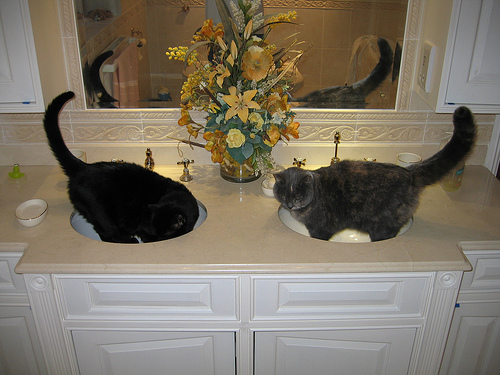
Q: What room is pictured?
A: It is a bathroom.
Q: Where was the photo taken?
A: It was taken at the bathroom.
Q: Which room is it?
A: It is a bathroom.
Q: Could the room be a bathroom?
A: Yes, it is a bathroom.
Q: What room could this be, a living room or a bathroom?
A: It is a bathroom.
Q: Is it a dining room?
A: No, it is a bathroom.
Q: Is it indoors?
A: Yes, it is indoors.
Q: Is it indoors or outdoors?
A: It is indoors.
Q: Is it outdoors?
A: No, it is indoors.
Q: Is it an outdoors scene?
A: No, it is indoors.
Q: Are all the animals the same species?
A: Yes, all the animals are cats.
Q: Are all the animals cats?
A: Yes, all the animals are cats.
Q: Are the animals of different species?
A: No, all the animals are cats.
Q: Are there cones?
A: No, there are no cones.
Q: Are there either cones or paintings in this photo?
A: No, there are no cones or paintings.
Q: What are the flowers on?
A: The flowers are on the counter.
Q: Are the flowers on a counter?
A: Yes, the flowers are on a counter.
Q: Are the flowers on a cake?
A: No, the flowers are on a counter.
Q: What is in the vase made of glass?
A: The flowers are in the vase.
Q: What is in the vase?
A: The flowers are in the vase.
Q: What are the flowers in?
A: The flowers are in the vase.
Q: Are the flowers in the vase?
A: Yes, the flowers are in the vase.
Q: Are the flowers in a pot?
A: No, the flowers are in the vase.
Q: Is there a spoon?
A: No, there are no spoons.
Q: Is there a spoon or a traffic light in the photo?
A: No, there are no spoons or traffic lights.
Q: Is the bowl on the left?
A: Yes, the bowl is on the left of the image.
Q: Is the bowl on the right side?
A: No, the bowl is on the left of the image.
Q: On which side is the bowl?
A: The bowl is on the left of the image.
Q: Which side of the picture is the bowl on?
A: The bowl is on the left of the image.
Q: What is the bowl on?
A: The bowl is on the counter.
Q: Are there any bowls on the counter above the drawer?
A: Yes, there is a bowl on the counter.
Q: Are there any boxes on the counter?
A: No, there is a bowl on the counter.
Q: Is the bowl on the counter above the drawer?
A: Yes, the bowl is on the counter.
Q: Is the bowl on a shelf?
A: No, the bowl is on the counter.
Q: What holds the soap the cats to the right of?
A: The bowl holds the soap.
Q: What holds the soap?
A: The bowl holds the soap.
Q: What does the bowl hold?
A: The bowl holds the soap.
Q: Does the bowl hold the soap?
A: Yes, the bowl holds the soap.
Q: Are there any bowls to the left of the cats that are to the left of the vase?
A: Yes, there is a bowl to the left of the cats.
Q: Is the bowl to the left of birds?
A: No, the bowl is to the left of the cats.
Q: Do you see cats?
A: Yes, there are cats.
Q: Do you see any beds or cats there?
A: Yes, there are cats.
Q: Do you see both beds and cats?
A: No, there are cats but no beds.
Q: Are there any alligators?
A: No, there are no alligators.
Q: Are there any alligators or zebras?
A: No, there are no alligators or zebras.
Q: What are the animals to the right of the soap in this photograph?
A: The animals are cats.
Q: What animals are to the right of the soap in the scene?
A: The animals are cats.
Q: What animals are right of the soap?
A: The animals are cats.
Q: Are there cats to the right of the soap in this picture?
A: Yes, there are cats to the right of the soap.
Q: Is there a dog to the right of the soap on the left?
A: No, there are cats to the right of the soap.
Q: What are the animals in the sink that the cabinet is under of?
A: The animals are cats.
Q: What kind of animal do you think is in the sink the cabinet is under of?
A: The animals are cats.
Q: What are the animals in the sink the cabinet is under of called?
A: The animals are cats.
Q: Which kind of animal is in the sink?
A: The animals are cats.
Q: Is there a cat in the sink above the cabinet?
A: Yes, there are cats in the sink.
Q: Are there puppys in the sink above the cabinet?
A: No, there are cats in the sink.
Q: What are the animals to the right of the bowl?
A: The animals are cats.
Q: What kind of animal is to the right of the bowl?
A: The animals are cats.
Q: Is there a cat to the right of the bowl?
A: Yes, there are cats to the right of the bowl.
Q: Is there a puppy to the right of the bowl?
A: No, there are cats to the right of the bowl.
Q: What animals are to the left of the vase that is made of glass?
A: The animals are cats.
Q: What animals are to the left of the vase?
A: The animals are cats.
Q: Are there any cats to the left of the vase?
A: Yes, there are cats to the left of the vase.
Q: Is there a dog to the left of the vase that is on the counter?
A: No, there are cats to the left of the vase.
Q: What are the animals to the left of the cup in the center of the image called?
A: The animals are cats.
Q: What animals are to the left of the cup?
A: The animals are cats.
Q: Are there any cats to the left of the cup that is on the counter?
A: Yes, there are cats to the left of the cup.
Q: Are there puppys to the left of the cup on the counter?
A: No, there are cats to the left of the cup.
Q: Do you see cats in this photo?
A: Yes, there is a cat.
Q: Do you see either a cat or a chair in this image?
A: Yes, there is a cat.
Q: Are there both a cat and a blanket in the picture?
A: No, there is a cat but no blankets.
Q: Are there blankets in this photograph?
A: No, there are no blankets.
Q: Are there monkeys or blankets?
A: No, there are no blankets or monkeys.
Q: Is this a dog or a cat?
A: This is a cat.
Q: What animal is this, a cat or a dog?
A: This is a cat.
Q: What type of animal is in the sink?
A: The animal is a cat.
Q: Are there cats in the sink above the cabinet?
A: Yes, there is a cat in the sink.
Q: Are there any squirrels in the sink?
A: No, there is a cat in the sink.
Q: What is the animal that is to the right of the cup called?
A: The animal is a cat.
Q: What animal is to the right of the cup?
A: The animal is a cat.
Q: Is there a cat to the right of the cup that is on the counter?
A: Yes, there is a cat to the right of the cup.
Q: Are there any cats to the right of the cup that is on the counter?
A: Yes, there is a cat to the right of the cup.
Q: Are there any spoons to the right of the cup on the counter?
A: No, there is a cat to the right of the cup.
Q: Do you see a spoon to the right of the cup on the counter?
A: No, there is a cat to the right of the cup.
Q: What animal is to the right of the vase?
A: The animal is a cat.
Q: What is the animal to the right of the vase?
A: The animal is a cat.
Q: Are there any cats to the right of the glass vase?
A: Yes, there is a cat to the right of the vase.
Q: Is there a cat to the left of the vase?
A: No, the cat is to the right of the vase.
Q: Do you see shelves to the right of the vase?
A: No, there is a cat to the right of the vase.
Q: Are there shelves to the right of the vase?
A: No, there is a cat to the right of the vase.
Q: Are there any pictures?
A: No, there are no pictures.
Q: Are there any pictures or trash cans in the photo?
A: No, there are no pictures or trash cans.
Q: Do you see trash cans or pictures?
A: No, there are no pictures or trash cans.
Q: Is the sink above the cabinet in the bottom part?
A: Yes, the sink is above the cabinet.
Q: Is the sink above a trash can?
A: No, the sink is above the cabinet.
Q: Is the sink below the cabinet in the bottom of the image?
A: No, the sink is above the cabinet.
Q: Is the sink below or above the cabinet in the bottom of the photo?
A: The sink is above the cabinet.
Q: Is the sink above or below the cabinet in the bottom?
A: The sink is above the cabinet.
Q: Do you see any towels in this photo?
A: Yes, there is a towel.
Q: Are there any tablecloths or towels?
A: Yes, there is a towel.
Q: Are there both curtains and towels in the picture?
A: No, there is a towel but no curtains.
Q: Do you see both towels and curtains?
A: No, there is a towel but no curtains.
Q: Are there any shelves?
A: No, there are no shelves.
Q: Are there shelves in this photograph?
A: No, there are no shelves.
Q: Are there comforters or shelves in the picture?
A: No, there are no shelves or comforters.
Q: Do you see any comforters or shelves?
A: No, there are no shelves or comforters.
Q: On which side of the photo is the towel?
A: The towel is on the left of the image.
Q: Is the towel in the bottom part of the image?
A: No, the towel is in the top of the image.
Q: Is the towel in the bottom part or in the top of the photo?
A: The towel is in the top of the image.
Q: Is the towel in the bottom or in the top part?
A: The towel is in the top of the image.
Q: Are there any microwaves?
A: No, there are no microwaves.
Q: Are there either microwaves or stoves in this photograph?
A: No, there are no microwaves or stoves.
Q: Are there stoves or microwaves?
A: No, there are no microwaves or stoves.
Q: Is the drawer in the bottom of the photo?
A: Yes, the drawer is in the bottom of the image.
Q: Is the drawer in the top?
A: No, the drawer is in the bottom of the image.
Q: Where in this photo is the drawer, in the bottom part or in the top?
A: The drawer is in the bottom of the image.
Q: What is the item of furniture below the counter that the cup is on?
A: The piece of furniture is a drawer.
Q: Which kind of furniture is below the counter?
A: The piece of furniture is a drawer.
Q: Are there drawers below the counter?
A: Yes, there is a drawer below the counter.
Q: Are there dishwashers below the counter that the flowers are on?
A: No, there is a drawer below the counter.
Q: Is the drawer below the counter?
A: Yes, the drawer is below the counter.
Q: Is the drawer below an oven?
A: No, the drawer is below the counter.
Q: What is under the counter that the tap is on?
A: The drawer is under the counter.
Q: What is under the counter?
A: The drawer is under the counter.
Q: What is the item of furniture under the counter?
A: The piece of furniture is a drawer.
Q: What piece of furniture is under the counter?
A: The piece of furniture is a drawer.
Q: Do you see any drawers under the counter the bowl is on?
A: Yes, there is a drawer under the counter.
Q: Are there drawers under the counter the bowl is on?
A: Yes, there is a drawer under the counter.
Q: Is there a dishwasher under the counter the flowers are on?
A: No, there is a drawer under the counter.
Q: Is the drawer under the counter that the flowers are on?
A: Yes, the drawer is under the counter.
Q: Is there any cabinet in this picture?
A: Yes, there is a cabinet.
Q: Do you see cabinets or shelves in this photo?
A: Yes, there is a cabinet.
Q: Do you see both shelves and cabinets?
A: No, there is a cabinet but no shelves.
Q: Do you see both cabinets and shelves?
A: No, there is a cabinet but no shelves.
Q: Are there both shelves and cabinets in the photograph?
A: No, there is a cabinet but no shelves.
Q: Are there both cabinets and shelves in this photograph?
A: No, there is a cabinet but no shelves.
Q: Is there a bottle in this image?
A: No, there are no bottles.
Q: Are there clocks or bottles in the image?
A: No, there are no bottles or clocks.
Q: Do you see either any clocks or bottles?
A: No, there are no bottles or clocks.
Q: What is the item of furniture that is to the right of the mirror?
A: The piece of furniture is a cabinet.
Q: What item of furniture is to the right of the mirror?
A: The piece of furniture is a cabinet.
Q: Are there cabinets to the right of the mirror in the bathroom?
A: Yes, there is a cabinet to the right of the mirror.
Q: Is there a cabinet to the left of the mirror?
A: No, the cabinet is to the right of the mirror.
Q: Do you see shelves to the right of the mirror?
A: No, there is a cabinet to the right of the mirror.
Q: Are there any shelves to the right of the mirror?
A: No, there is a cabinet to the right of the mirror.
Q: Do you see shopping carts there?
A: No, there are no shopping carts.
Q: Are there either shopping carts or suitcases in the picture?
A: No, there are no shopping carts or suitcases.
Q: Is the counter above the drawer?
A: Yes, the counter is above the drawer.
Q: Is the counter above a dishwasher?
A: No, the counter is above the drawer.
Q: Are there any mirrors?
A: Yes, there is a mirror.